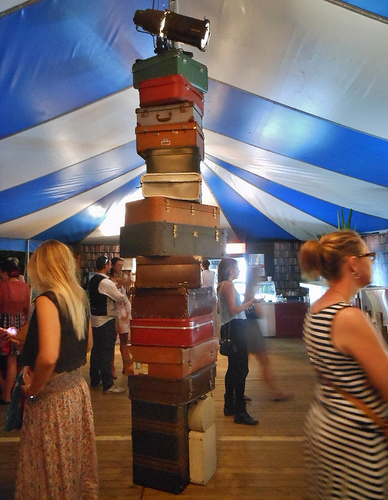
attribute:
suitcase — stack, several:
[104, 52, 249, 483]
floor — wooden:
[212, 439, 292, 495]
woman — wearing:
[4, 214, 139, 499]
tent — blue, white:
[1, 43, 124, 217]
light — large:
[91, 6, 231, 67]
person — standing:
[175, 225, 289, 445]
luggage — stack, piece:
[82, 41, 245, 480]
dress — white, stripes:
[111, 296, 140, 341]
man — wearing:
[58, 218, 159, 400]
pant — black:
[198, 323, 265, 437]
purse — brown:
[197, 316, 251, 372]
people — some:
[73, 213, 299, 387]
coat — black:
[27, 293, 107, 372]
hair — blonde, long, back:
[49, 227, 86, 285]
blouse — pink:
[2, 404, 116, 494]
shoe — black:
[209, 397, 271, 425]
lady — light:
[186, 189, 317, 423]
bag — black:
[191, 313, 245, 371]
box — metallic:
[162, 385, 256, 483]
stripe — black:
[303, 389, 387, 479]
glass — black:
[351, 242, 370, 270]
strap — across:
[260, 308, 373, 495]